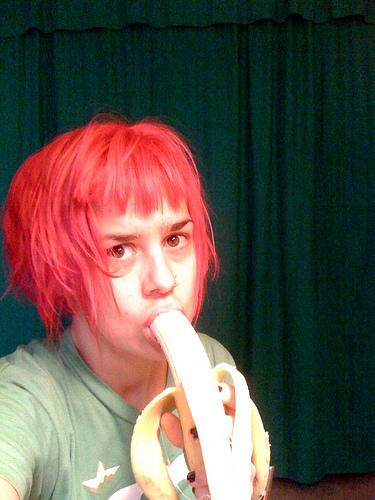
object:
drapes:
[1, 0, 375, 489]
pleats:
[224, 30, 340, 487]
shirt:
[0, 329, 238, 500]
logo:
[83, 459, 122, 499]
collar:
[54, 327, 146, 426]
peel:
[128, 386, 183, 499]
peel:
[212, 361, 254, 500]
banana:
[129, 308, 273, 500]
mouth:
[142, 304, 187, 352]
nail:
[186, 470, 197, 485]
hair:
[0, 104, 222, 349]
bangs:
[73, 110, 200, 220]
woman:
[0, 103, 273, 500]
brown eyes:
[104, 239, 139, 261]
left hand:
[159, 380, 270, 500]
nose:
[141, 232, 176, 298]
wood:
[271, 475, 373, 500]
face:
[77, 176, 201, 366]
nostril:
[143, 279, 160, 296]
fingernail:
[187, 424, 201, 444]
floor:
[264, 471, 374, 500]